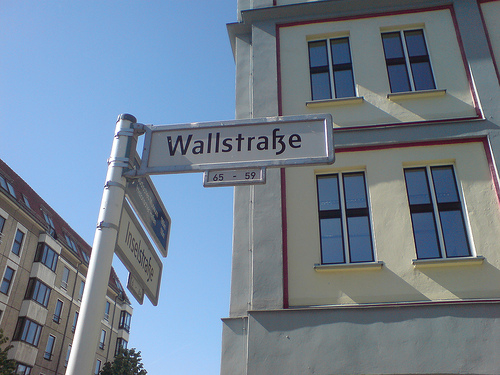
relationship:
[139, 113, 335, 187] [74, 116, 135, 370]
sign on post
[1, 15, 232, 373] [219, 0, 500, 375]
sky above building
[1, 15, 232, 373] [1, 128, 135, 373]
sky above buildings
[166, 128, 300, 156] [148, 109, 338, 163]
black writing on sign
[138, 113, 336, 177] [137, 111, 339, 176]
silver border on sign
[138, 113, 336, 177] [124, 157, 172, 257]
silver border on sign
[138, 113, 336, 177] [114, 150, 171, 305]
silver border on sign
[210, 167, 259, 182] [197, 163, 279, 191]
numbers on sign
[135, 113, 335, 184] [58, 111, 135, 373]
sign on post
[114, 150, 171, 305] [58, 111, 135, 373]
sign on post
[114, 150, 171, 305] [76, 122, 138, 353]
sign on post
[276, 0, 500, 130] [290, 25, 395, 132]
red trim in window frame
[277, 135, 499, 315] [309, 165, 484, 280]
red trim around window section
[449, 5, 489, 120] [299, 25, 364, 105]
red trim around window